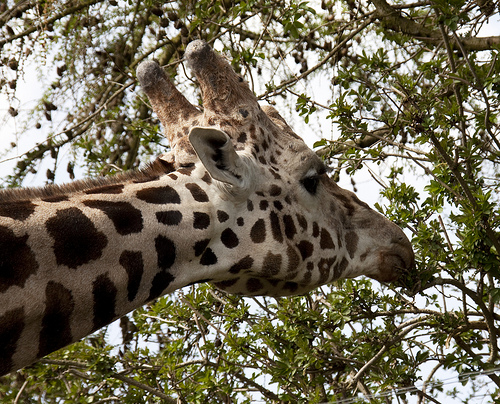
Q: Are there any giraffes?
A: Yes, there is a giraffe.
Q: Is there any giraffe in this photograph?
A: Yes, there is a giraffe.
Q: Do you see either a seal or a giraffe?
A: Yes, there is a giraffe.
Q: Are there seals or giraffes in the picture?
A: Yes, there is a giraffe.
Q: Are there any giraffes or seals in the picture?
A: Yes, there is a giraffe.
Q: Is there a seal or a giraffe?
A: Yes, there is a giraffe.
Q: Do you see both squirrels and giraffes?
A: No, there is a giraffe but no squirrels.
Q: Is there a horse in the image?
A: No, there are no horses.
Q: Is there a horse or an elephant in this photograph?
A: No, there are no horses or elephants.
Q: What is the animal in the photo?
A: The animal is a giraffe.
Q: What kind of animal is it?
A: The animal is a giraffe.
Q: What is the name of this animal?
A: That is a giraffe.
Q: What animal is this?
A: That is a giraffe.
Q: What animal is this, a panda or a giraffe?
A: That is a giraffe.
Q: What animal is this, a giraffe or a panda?
A: That is a giraffe.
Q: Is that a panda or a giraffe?
A: That is a giraffe.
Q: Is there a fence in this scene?
A: No, there are no fences.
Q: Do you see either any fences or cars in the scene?
A: No, there are no fences or cars.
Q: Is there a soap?
A: No, there are no soaps.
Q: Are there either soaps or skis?
A: No, there are no soaps or skis.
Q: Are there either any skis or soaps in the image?
A: No, there are no soaps or skis.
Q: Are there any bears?
A: No, there are no bears.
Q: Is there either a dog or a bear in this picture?
A: No, there are no bears or dogs.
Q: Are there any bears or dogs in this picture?
A: No, there are no bears or dogs.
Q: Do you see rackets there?
A: No, there are no rackets.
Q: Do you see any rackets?
A: No, there are no rackets.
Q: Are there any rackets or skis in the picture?
A: No, there are no rackets or skis.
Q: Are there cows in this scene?
A: No, there are no cows.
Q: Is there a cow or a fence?
A: No, there are no cows or fences.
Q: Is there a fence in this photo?
A: No, there are no fences.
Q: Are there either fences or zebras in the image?
A: No, there are no fences or zebras.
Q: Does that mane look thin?
A: Yes, the mane is thin.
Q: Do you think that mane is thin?
A: Yes, the mane is thin.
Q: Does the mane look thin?
A: Yes, the mane is thin.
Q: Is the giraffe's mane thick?
A: No, the mane is thin.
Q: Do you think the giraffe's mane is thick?
A: No, the mane is thin.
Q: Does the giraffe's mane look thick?
A: No, the mane is thin.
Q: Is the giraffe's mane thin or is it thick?
A: The mane is thin.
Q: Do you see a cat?
A: No, there are no cats.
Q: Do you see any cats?
A: No, there are no cats.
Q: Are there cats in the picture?
A: No, there are no cats.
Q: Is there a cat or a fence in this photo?
A: No, there are no cats or fences.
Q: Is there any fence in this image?
A: No, there are no fences.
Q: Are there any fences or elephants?
A: No, there are no fences or elephants.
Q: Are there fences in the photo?
A: No, there are no fences.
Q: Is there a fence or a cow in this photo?
A: No, there are no fences or cows.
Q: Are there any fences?
A: No, there are no fences.